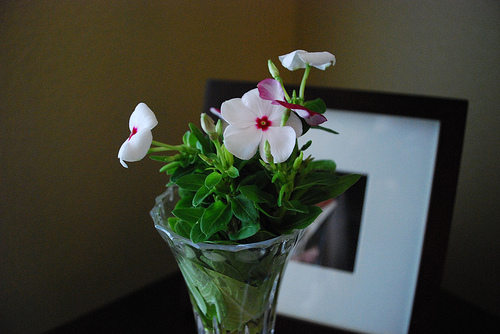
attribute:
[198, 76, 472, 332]
frame — square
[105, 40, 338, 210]
flower — purple, facing up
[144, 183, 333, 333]
vase — clear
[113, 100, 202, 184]
flower — purple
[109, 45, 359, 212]
flowers — fresh, white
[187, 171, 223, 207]
leaf — green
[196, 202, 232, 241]
leaf — green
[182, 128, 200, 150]
leaf — green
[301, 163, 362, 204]
leaf — green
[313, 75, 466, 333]
picture — white, black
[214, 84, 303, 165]
flower — white, purple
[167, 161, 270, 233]
leaves — vibrant, small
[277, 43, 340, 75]
flower — white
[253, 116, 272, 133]
center — pink, red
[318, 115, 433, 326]
inset — white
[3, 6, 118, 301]
wall — gray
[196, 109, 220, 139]
bud — green, closed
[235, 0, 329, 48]
corner — dark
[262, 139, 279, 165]
bud — white